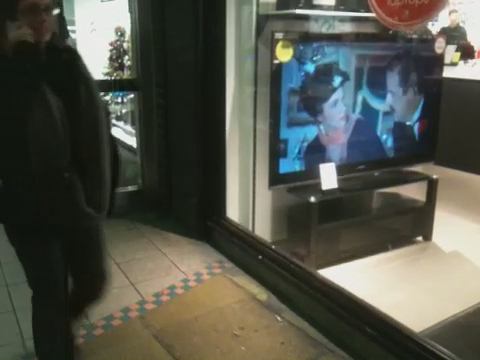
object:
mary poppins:
[297, 62, 391, 172]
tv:
[268, 30, 438, 186]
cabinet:
[288, 170, 440, 271]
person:
[2, 1, 124, 360]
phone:
[6, 9, 39, 54]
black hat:
[300, 60, 351, 106]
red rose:
[419, 121, 429, 134]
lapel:
[390, 93, 433, 160]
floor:
[319, 162, 480, 360]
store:
[442, 2, 476, 299]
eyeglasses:
[7, 4, 62, 17]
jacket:
[2, 37, 120, 242]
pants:
[3, 217, 110, 359]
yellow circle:
[275, 39, 296, 64]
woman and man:
[298, 49, 433, 173]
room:
[0, 3, 473, 360]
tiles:
[442, 186, 472, 219]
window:
[65, 0, 154, 183]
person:
[110, 56, 126, 106]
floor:
[0, 215, 344, 360]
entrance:
[141, 0, 222, 227]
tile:
[149, 296, 294, 359]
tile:
[118, 246, 183, 287]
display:
[254, 9, 444, 270]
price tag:
[316, 161, 341, 191]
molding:
[213, 211, 480, 360]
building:
[0, 1, 480, 359]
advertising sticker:
[366, 0, 452, 31]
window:
[428, 1, 479, 81]